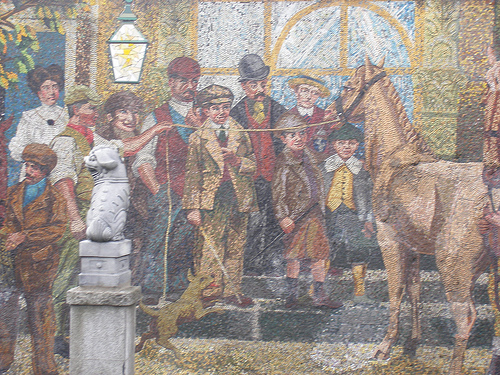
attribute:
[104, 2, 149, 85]
lantern — glass, metal, hanging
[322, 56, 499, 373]
horse — brown, looking left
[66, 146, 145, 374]
statue — white, stone, gray, a dog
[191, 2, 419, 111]
window — large, arched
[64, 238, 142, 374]
base — gray, stone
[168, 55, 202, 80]
hat — red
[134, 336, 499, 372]
ground — brown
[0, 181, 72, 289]
jacket — brown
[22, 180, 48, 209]
scarf — blue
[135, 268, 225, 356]
dog — brown, small, jumping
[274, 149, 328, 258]
suit — brown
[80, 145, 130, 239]
dog — stone, looking left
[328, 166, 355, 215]
vest — yellow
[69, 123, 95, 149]
scarf — red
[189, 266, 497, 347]
steps — stone